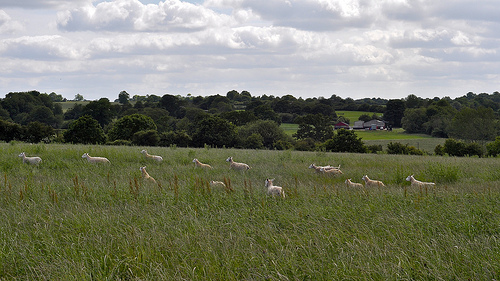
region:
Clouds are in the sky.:
[35, 10, 342, 80]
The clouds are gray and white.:
[64, 10, 306, 78]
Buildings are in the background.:
[323, 108, 397, 133]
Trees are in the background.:
[0, 84, 497, 167]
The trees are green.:
[135, 110, 230, 134]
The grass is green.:
[87, 201, 285, 268]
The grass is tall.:
[84, 209, 264, 277]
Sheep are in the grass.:
[11, 137, 455, 218]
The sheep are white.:
[14, 140, 451, 213]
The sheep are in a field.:
[0, 131, 494, 278]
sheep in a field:
[7, 137, 466, 200]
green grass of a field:
[24, 226, 467, 273]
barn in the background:
[334, 111, 395, 133]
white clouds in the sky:
[37, 3, 219, 36]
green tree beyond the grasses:
[59, 112, 110, 147]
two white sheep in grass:
[303, 160, 353, 177]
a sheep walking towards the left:
[11, 143, 61, 174]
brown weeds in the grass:
[125, 169, 146, 201]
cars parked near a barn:
[362, 125, 392, 134]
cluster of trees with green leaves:
[387, 85, 498, 141]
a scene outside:
[2, 7, 497, 279]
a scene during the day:
[3, 2, 498, 267]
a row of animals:
[1, 137, 466, 217]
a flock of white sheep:
[0, 145, 447, 215]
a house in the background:
[340, 110, 393, 143]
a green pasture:
[0, 127, 497, 272]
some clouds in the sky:
[8, 0, 490, 95]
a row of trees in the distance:
[5, 88, 497, 156]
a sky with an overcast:
[3, 2, 498, 92]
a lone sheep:
[252, 167, 301, 212]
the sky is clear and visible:
[27, 19, 292, 174]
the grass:
[122, 149, 184, 263]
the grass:
[173, 131, 268, 275]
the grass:
[165, 191, 215, 266]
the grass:
[92, 136, 210, 271]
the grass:
[160, 164, 230, 273]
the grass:
[211, 185, 221, 271]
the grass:
[187, 205, 221, 265]